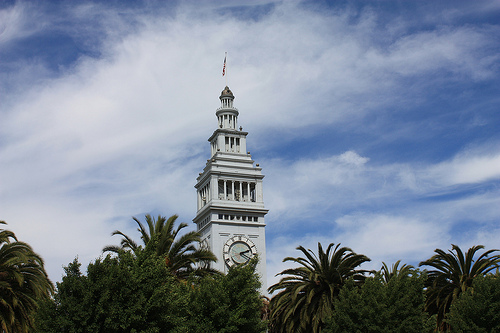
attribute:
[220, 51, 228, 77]
flag — american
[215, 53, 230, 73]
flag — american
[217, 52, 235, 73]
flag — american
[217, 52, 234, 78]
flag — american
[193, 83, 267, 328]
tower — clock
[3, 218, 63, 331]
tree — green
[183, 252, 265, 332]
tree — green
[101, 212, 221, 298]
tree — green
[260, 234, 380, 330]
tree — green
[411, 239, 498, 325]
tree — green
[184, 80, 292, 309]
steeple — tall, white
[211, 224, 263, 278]
clock face — round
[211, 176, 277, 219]
pillars — white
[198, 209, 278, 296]
clock — large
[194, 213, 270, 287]
clock — large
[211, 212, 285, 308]
clock — large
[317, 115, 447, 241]
sky — blue